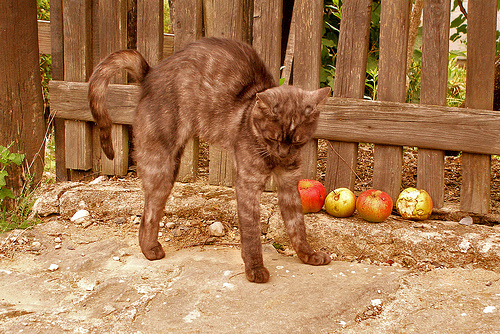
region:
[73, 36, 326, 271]
The cat is stretching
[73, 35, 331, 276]
The cat is white and brown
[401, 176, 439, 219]
The apple has been eaten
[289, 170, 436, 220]
There are four apples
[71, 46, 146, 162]
The tail of the cat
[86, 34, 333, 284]
Cat arching its back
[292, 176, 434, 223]
Four apples in front of the fence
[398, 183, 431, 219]
Partially-eaten, rotting apple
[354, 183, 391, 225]
Red apple in front of the fence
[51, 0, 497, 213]
Brown wooden fence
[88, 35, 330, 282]
Brown cat in front of brown fence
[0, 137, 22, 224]
Green weed beside the fence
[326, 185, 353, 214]
Yellow apple between two red apples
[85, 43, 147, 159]
Cats curved tail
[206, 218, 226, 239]
Small stone on the ground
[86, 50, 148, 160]
Light brown and brown cat tail.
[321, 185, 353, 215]
The smallest yellowest apple.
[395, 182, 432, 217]
Rotten looking very large yellow apple.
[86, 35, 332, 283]
A brown cat.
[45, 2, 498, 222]
A brown fence.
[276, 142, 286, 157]
Brown cat nose.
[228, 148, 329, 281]
Cats brown front arms.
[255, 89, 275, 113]
Right cat's ear.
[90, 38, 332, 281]
a tortoiseshell colored cat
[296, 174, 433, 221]
four apples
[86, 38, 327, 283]
red apple beside the cat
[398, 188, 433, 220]
damaged yellow apple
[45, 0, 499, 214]
a wooden slate fence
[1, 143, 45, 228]
a tuft of grass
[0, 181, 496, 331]
the brown dirt and white rocks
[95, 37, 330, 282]
the cats four paws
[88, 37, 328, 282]
the cats two ears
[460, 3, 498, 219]
brown wooden fence board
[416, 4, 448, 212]
brown wooden fence board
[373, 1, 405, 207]
brown wooden fence board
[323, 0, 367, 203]
brown wooden fence board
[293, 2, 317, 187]
brown wooden fence board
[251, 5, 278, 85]
brown wooden fence board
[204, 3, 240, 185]
brown wooden fence board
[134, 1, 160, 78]
brown wooden fence board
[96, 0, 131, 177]
brown wooden fence board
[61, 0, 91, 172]
brown wooden fence board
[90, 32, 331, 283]
a cat with a humped back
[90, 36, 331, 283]
cat in a Halloween pose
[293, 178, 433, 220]
a row of heirloom tomatoes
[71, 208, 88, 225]
a stone on the slab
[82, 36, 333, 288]
Brown cat next to an apple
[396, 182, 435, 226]
Apple leaning on a wooden post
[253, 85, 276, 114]
ear of a cat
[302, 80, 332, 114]
ear of a cat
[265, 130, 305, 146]
eyes of a cat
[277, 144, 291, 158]
nose of a cat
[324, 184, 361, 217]
apple on a ledge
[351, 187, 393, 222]
apple on a ledge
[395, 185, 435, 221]
apple on a ledge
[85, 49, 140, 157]
tail of a cat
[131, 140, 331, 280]
legs of a cat